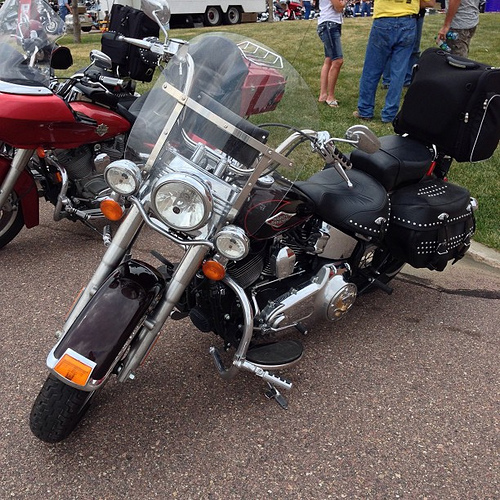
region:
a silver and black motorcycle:
[26, 35, 484, 450]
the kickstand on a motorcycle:
[258, 380, 289, 416]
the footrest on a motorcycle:
[235, 353, 296, 394]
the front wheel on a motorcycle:
[28, 253, 169, 443]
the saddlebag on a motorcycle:
[393, 183, 484, 273]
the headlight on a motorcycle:
[149, 175, 214, 235]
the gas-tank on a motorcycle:
[233, 184, 309, 244]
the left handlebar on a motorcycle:
[269, 117, 351, 190]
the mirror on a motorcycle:
[342, 122, 384, 157]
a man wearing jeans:
[355, 0, 421, 117]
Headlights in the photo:
[102, 152, 250, 256]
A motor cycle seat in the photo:
[300, 164, 393, 237]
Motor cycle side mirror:
[346, 123, 379, 153]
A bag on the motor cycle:
[399, 175, 484, 272]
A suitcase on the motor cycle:
[390, 42, 497, 166]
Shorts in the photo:
[308, 17, 353, 59]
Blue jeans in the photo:
[355, 20, 417, 118]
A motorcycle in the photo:
[25, 29, 485, 445]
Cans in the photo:
[432, 19, 462, 53]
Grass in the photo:
[252, 23, 294, 47]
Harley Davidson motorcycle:
[31, 39, 494, 443]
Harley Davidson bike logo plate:
[263, 207, 298, 232]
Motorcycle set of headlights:
[93, 143, 249, 274]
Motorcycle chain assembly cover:
[244, 259, 386, 339]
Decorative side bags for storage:
[381, 177, 486, 273]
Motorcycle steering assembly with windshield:
[112, 15, 368, 239]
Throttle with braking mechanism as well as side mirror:
[286, 118, 382, 195]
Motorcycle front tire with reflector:
[29, 234, 162, 471]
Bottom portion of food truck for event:
[63, 0, 293, 37]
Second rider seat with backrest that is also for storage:
[358, 25, 498, 195]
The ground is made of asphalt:
[111, 422, 497, 477]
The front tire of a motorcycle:
[30, 270, 167, 456]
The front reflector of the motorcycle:
[46, 346, 101, 393]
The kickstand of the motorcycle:
[250, 353, 299, 408]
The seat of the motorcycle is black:
[295, 153, 396, 238]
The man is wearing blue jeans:
[355, 13, 423, 126]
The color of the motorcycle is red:
[0, 69, 127, 227]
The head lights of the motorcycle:
[101, 143, 256, 273]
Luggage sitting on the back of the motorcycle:
[388, 42, 497, 179]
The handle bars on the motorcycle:
[113, 11, 372, 218]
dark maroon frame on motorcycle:
[6, 79, 453, 430]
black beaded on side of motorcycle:
[239, 152, 497, 330]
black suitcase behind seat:
[375, 22, 495, 171]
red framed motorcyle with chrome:
[9, 52, 164, 250]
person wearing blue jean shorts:
[304, 0, 346, 127]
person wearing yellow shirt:
[356, 0, 424, 133]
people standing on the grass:
[297, 2, 498, 143]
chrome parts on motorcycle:
[76, 118, 349, 381]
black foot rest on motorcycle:
[216, 130, 363, 425]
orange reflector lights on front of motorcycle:
[72, 167, 230, 282]